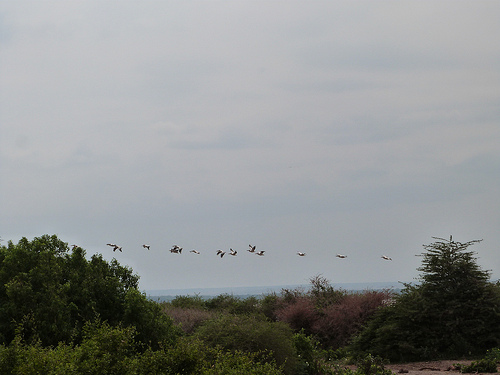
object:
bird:
[381, 253, 393, 261]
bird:
[336, 252, 347, 258]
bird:
[296, 250, 306, 257]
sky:
[0, 0, 500, 290]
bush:
[345, 234, 499, 362]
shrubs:
[455, 357, 499, 371]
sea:
[143, 286, 403, 303]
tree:
[0, 233, 176, 352]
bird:
[256, 249, 265, 257]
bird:
[107, 242, 122, 252]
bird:
[248, 244, 256, 253]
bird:
[229, 246, 237, 258]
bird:
[215, 247, 225, 258]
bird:
[188, 248, 201, 254]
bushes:
[273, 295, 318, 333]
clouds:
[0, 0, 499, 290]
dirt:
[326, 358, 499, 374]